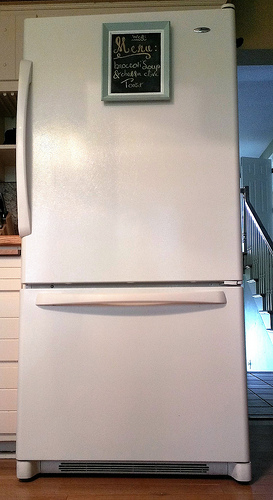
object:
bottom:
[15, 287, 250, 486]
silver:
[193, 26, 211, 33]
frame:
[101, 18, 173, 104]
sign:
[112, 35, 160, 88]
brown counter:
[0, 233, 20, 256]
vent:
[58, 463, 210, 472]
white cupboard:
[1, 0, 222, 92]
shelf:
[1, 6, 22, 89]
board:
[100, 20, 173, 105]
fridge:
[12, 0, 251, 484]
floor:
[0, 417, 273, 499]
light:
[243, 309, 273, 374]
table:
[0, 227, 18, 244]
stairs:
[241, 188, 272, 338]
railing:
[240, 138, 271, 321]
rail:
[240, 143, 273, 337]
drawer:
[0, 259, 22, 291]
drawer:
[0, 290, 19, 362]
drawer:
[0, 361, 18, 434]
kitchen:
[1, 1, 273, 497]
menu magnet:
[99, 21, 170, 103]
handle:
[14, 60, 37, 239]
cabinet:
[1, 5, 27, 84]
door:
[14, 8, 244, 287]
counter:
[0, 235, 22, 257]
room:
[235, 26, 271, 321]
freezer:
[14, 284, 254, 487]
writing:
[113, 33, 161, 90]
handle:
[27, 286, 227, 308]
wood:
[0, 471, 272, 500]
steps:
[236, 185, 272, 345]